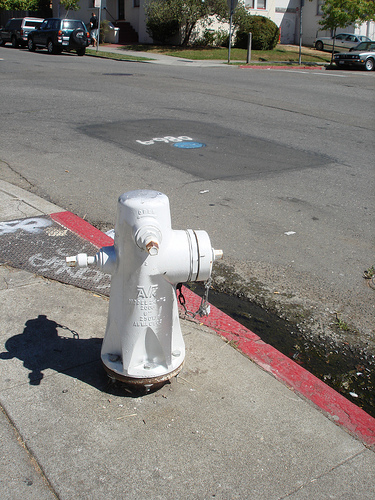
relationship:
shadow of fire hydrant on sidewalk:
[0, 303, 171, 413] [263, 356, 337, 442]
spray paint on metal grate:
[1, 213, 51, 244] [0, 213, 109, 297]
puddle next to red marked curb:
[185, 271, 375, 420] [58, 206, 374, 448]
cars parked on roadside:
[30, 14, 109, 55] [202, 216, 343, 412]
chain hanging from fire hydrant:
[174, 271, 223, 325] [66, 188, 227, 394]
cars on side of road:
[26, 14, 94, 59] [285, 281, 336, 360]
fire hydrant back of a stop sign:
[66, 188, 227, 394] [221, 0, 235, 65]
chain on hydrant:
[174, 271, 219, 324] [56, 185, 230, 394]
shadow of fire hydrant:
[3, 303, 131, 402] [66, 188, 227, 394]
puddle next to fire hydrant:
[288, 332, 371, 401] [92, 196, 251, 441]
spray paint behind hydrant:
[1, 213, 56, 240] [56, 185, 230, 394]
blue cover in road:
[173, 139, 205, 150] [0, 35, 375, 419]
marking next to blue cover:
[134, 132, 197, 147] [173, 139, 205, 150]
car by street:
[333, 38, 373, 69] [1, 40, 374, 415]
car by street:
[313, 29, 366, 56] [1, 40, 374, 415]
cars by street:
[26, 14, 94, 59] [1, 40, 374, 415]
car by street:
[2, 11, 43, 46] [1, 40, 374, 415]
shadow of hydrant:
[0, 303, 171, 413] [56, 185, 230, 394]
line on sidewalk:
[196, 298, 361, 435] [0, 178, 374, 498]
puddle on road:
[185, 271, 375, 420] [223, 118, 338, 291]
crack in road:
[2, 156, 51, 198] [0, 35, 375, 419]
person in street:
[88, 11, 100, 47] [172, 99, 360, 246]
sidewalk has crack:
[0, 178, 374, 498] [1, 186, 47, 223]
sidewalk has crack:
[0, 178, 374, 498] [0, 276, 53, 293]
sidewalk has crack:
[0, 178, 374, 498] [0, 354, 101, 393]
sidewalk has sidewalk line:
[0, 178, 374, 498] [2, 402, 62, 498]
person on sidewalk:
[88, 11, 100, 47] [87, 43, 336, 68]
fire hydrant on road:
[66, 188, 227, 394] [5, 52, 372, 389]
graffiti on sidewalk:
[20, 208, 57, 275] [24, 186, 284, 427]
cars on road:
[26, 14, 94, 59] [86, 71, 246, 105]